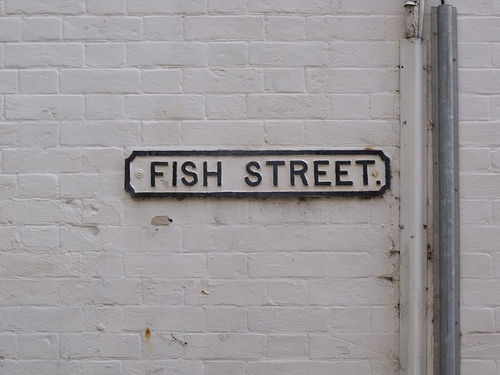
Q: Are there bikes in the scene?
A: No, there are no bikes.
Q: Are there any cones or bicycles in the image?
A: No, there are no bicycles or cones.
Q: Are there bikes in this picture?
A: No, there are no bikes.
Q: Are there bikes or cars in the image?
A: No, there are no bikes or cars.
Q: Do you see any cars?
A: No, there are no cars.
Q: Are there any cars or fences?
A: No, there are no cars or fences.